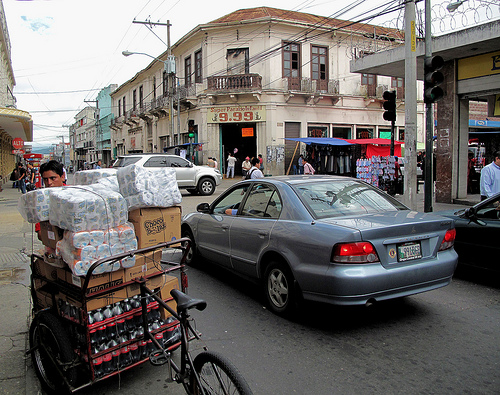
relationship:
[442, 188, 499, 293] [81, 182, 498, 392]
black car on street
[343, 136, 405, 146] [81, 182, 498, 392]
red roof across street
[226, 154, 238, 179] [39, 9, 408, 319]
man standing in front of building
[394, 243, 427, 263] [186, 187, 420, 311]
license plate on car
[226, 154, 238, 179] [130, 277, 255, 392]
man behind bicycle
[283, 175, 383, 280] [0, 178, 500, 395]
car driving down road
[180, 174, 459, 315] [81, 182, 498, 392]
car driving down street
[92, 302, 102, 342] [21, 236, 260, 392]
bottle on cart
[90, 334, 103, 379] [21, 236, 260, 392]
bottle on cart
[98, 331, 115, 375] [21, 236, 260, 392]
bottle on cart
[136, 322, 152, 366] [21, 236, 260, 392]
bottle on cart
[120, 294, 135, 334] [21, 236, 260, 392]
bottle on cart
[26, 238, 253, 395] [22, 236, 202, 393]
bike behind cart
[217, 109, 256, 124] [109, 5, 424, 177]
red numbers on building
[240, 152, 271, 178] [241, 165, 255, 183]
man wearing backpack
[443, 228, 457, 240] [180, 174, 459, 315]
light engaged on car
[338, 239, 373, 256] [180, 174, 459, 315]
light engaged on car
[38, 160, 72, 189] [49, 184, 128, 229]
man pushing goods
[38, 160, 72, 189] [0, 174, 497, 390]
man on street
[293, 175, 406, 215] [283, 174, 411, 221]
reflection off back window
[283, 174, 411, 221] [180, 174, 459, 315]
back window of car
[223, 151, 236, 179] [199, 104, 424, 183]
man gathered in front of store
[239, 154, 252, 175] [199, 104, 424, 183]
man gathered in front of store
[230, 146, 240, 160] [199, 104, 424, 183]
man gathered in front of store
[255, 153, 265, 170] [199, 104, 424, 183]
man gathered in front of store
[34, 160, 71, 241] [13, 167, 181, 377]
man delivering goods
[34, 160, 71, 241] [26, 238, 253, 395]
man has bike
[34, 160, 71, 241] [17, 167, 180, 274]
man has paper towels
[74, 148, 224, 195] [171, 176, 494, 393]
suv on street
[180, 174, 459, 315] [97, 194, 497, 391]
car stopped on road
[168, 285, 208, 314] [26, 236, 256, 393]
seat on bike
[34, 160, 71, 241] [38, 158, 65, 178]
man with hair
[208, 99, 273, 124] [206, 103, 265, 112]
sign with letters